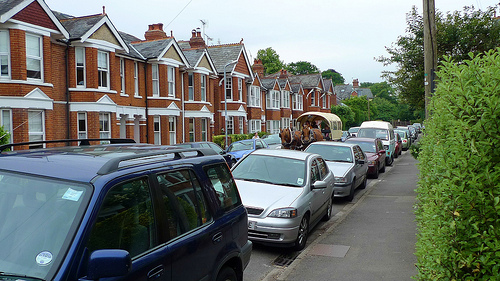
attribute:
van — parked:
[358, 118, 402, 165]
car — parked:
[346, 134, 389, 178]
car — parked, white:
[301, 140, 373, 202]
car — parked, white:
[213, 144, 340, 251]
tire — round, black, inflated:
[321, 191, 339, 224]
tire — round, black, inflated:
[289, 212, 314, 254]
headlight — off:
[266, 203, 298, 222]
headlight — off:
[330, 174, 348, 188]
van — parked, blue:
[0, 134, 258, 279]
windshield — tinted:
[0, 168, 96, 280]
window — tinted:
[201, 159, 246, 215]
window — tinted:
[155, 162, 217, 248]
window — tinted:
[69, 173, 166, 280]